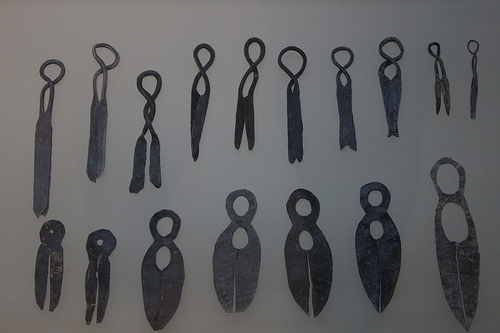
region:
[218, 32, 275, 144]
a drawing of a stik man.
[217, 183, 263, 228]
the head of a stick person.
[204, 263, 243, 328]
the right leg of a stick person.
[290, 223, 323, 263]
the body of a stick person.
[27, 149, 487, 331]
a group of stick people.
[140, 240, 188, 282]
the chest of a stick person.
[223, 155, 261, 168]
a section of a light surface.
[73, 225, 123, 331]
a deformed stick person.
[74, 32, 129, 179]
a poorly drawn stick person.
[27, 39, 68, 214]
a pair of scissors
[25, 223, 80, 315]
a pair of tweezers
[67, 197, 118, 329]
a crooked pair of tweezers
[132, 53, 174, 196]
pair of scissors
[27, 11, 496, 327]
bunch of scissors and tweezers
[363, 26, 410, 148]
pair of scissors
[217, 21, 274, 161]
a pair of curvy scissors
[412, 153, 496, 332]
a large pair of tweezers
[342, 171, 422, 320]
a medium size pair of tweezers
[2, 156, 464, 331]
bunch of tweezers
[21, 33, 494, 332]
collection of ancient scissors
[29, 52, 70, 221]
long antique metal object with loop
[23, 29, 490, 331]
group of antique scissors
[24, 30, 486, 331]
antique metal shearing tools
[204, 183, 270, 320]
rounded antique figure eight shaped tool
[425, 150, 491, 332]
long metal tool with handle in shape of number eight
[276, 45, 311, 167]
antique scissors tool with loop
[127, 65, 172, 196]
old twisted metal with loop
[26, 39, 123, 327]
four very old scissors or shears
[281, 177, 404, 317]
two ancient pairs of rounded shears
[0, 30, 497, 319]
image fo black ties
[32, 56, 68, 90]
black loop painted on sheet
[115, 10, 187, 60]
white background for drawings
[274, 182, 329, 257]
two white circles in drawing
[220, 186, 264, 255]
white circles in drawing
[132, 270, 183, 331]
black tip to drawing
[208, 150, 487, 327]
thick black drawings with loops